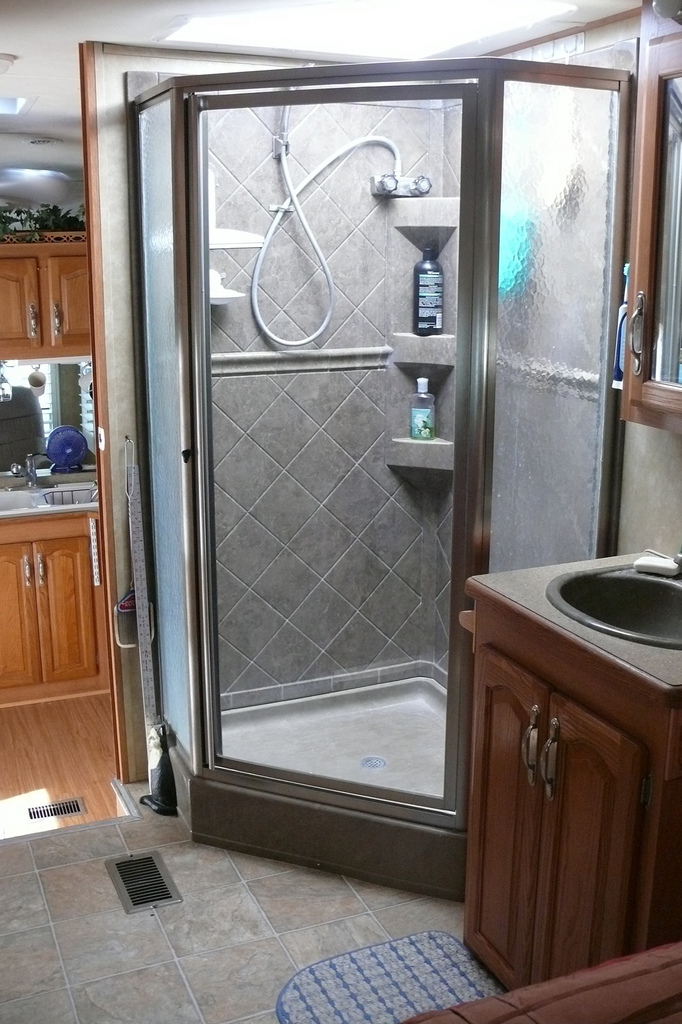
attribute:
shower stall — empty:
[131, 88, 631, 909]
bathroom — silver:
[201, 90, 500, 831]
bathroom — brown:
[469, 551, 675, 979]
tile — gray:
[18, 815, 462, 1020]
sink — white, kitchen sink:
[4, 479, 94, 515]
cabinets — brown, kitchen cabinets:
[2, 514, 109, 701]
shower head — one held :
[251, 58, 427, 361]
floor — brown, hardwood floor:
[3, 781, 571, 1020]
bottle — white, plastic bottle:
[413, 246, 443, 332]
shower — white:
[113, 46, 646, 908]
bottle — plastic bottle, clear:
[406, 373, 433, 439]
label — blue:
[406, 410, 433, 439]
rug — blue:
[277, 931, 499, 1022]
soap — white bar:
[632, 554, 680, 575]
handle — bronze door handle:
[520, 703, 543, 794]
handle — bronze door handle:
[542, 704, 558, 801]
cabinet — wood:
[458, 583, 663, 992]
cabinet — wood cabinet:
[1, 517, 96, 687]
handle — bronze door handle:
[37, 555, 45, 586]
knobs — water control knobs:
[368, 170, 431, 196]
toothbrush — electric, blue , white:
[612, 260, 634, 390]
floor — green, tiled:
[4, 790, 502, 1018]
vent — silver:
[108, 851, 182, 911]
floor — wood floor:
[1, 687, 136, 822]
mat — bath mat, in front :
[275, 933, 503, 1019]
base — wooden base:
[458, 591, 674, 978]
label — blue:
[408, 404, 435, 438]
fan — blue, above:
[46, 427, 84, 472]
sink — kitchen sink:
[0, 483, 99, 513]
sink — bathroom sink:
[470, 546, 679, 678]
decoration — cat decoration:
[139, 725, 178, 815]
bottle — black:
[388, 251, 461, 334]